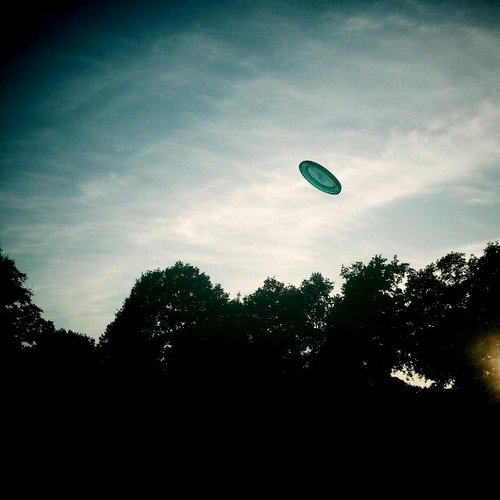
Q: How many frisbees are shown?
A: One.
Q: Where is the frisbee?
A: Above the treeline.